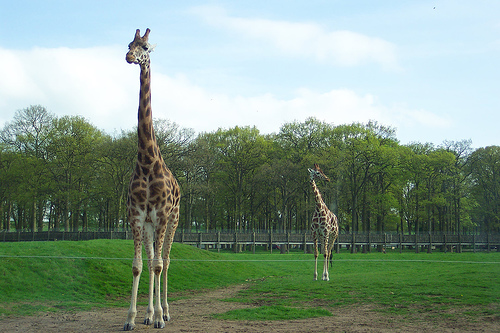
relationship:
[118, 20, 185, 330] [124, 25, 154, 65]
giraffe has head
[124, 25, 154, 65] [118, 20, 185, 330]
head of giraffe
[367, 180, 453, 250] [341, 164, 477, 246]
set of trees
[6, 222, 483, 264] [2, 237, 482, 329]
fence along enclosure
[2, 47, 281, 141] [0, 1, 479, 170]
clouds in sky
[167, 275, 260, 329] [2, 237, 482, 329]
dirt patch in enclosure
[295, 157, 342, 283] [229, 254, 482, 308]
giraffe walks in grass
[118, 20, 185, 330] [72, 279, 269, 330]
giraffe walks through path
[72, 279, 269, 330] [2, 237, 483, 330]
path worn into grass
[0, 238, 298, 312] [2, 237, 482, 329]
hill in enclosure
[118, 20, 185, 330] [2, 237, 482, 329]
giraffe in enclosure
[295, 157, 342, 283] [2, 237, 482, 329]
giraffe in enclosure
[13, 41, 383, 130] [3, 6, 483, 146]
clouds in sky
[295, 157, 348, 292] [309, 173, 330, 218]
giraffe has neck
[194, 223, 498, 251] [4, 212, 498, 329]
walkway at edge of enclosure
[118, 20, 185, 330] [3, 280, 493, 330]
giraffe standing on soil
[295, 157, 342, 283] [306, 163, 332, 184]
giraffe with head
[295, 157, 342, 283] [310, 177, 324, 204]
giraffe with neck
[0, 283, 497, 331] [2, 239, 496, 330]
patches in field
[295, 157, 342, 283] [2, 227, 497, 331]
giraffe in zoo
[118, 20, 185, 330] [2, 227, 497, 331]
giraffe in zoo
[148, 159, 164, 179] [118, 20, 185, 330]
spot on giraffe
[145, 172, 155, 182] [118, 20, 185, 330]
spot on giraffe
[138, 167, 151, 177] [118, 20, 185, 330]
spot on giraffe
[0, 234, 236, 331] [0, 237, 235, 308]
hill filled with grass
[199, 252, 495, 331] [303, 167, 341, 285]
ground next to giraffe